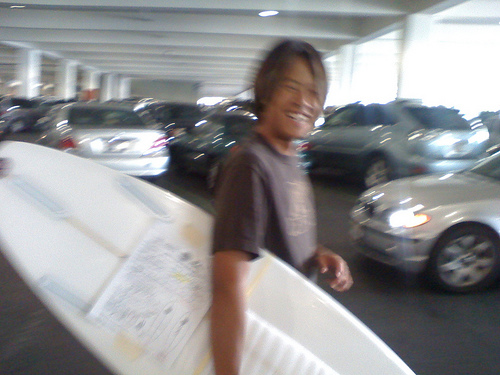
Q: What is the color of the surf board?
A: White.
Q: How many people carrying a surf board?
A: One.